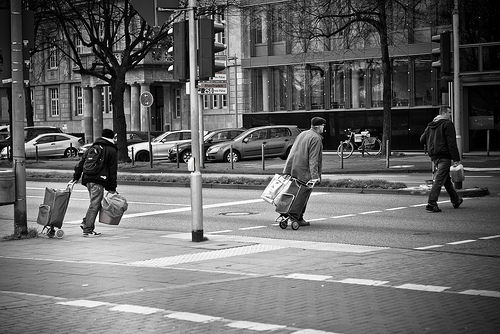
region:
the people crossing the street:
[253, 107, 473, 230]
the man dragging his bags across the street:
[263, 115, 330, 235]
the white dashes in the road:
[59, 292, 296, 332]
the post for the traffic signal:
[184, 0, 207, 237]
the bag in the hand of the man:
[97, 187, 131, 229]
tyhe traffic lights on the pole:
[165, 16, 227, 83]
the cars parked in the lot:
[125, 123, 298, 158]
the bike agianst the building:
[331, 123, 382, 163]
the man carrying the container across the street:
[419, 100, 466, 214]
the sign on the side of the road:
[136, 89, 162, 175]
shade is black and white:
[83, 80, 443, 326]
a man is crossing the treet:
[283, 137, 359, 273]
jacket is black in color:
[420, 110, 467, 153]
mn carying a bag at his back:
[73, 141, 150, 196]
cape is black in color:
[311, 107, 326, 133]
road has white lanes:
[316, 239, 426, 331]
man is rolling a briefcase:
[32, 132, 104, 259]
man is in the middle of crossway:
[267, 129, 342, 281]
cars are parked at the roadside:
[206, 117, 282, 162]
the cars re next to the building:
[233, 63, 353, 119]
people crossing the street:
[62, 73, 477, 255]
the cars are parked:
[31, 118, 291, 167]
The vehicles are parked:
[0, 124, 300, 160]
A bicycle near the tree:
[338, 128, 381, 156]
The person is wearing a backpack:
[82, 141, 106, 171]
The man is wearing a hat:
[308, 117, 325, 126]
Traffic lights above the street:
[168, 20, 222, 82]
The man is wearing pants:
[427, 159, 459, 201]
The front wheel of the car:
[224, 148, 237, 165]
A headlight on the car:
[209, 145, 218, 154]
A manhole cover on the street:
[224, 211, 250, 216]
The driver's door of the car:
[244, 127, 267, 156]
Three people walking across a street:
[36, 105, 467, 233]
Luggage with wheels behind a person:
[36, 183, 71, 239]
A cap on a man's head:
[308, 114, 327, 127]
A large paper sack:
[256, 173, 299, 211]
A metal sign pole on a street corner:
[182, 92, 207, 244]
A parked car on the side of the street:
[128, 125, 211, 156]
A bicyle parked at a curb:
[333, 128, 383, 158]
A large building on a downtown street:
[231, 8, 495, 163]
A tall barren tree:
[309, 3, 399, 153]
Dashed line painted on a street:
[266, 263, 493, 308]